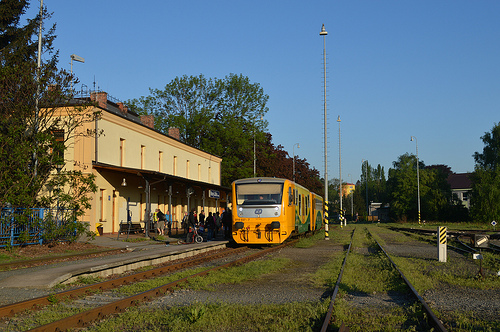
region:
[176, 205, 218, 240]
People waiting in a train station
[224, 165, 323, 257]
Green and Yellow commuter train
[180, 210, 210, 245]
Person holding a tricycle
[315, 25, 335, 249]
Yellow and black electric pole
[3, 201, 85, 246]
Blue metal fence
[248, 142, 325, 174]
Red fern trees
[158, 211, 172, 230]
Man with blue backpack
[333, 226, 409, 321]
Grass on railroad tracks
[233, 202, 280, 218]
Head lights on a commuter train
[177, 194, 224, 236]
People waiting to board a train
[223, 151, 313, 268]
front part of the train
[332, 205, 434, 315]
a big rail way track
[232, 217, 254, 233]
lights of the train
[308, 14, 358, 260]
a very long pillar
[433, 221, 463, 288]
a small mark on track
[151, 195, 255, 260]
group of people standing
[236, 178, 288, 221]
front glass of the train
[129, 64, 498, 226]
a beautiful group of trees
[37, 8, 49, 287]
a long electric poll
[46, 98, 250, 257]
a old rail way station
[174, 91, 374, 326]
the train is yellow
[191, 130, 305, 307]
the train is yellow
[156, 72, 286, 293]
the train is yellow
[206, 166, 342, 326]
the train is yellow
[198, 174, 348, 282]
yellow train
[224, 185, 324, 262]
yellow train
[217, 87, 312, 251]
yellow train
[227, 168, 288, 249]
yellow train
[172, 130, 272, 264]
yellow train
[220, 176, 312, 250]
a yellow train engine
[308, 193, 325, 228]
a yellow train car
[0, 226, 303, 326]
a set of train tracks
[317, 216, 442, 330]
a set of train tracks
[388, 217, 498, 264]
a set of train tracks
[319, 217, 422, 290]
moss covered train tracks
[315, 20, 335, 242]
a tall metal pole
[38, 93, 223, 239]
a yellow train station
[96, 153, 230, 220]
a passenger boarding shelter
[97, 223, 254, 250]
a passenger boarding platform